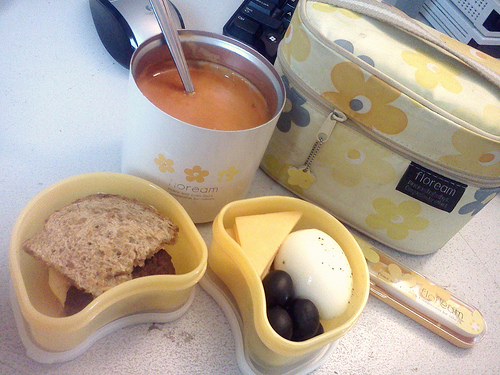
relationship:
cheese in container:
[231, 209, 304, 281] [208, 194, 370, 369]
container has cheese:
[208, 194, 370, 369] [231, 209, 304, 281]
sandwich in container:
[23, 192, 180, 315] [7, 170, 209, 353]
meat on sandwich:
[62, 248, 175, 315] [23, 192, 180, 315]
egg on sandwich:
[47, 269, 70, 307] [23, 192, 180, 315]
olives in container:
[265, 270, 324, 340] [208, 194, 370, 369]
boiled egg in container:
[273, 229, 352, 319] [208, 194, 370, 369]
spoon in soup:
[149, 0, 194, 94] [139, 55, 270, 130]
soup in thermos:
[139, 55, 270, 130] [125, 28, 287, 225]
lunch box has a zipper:
[260, 1, 499, 258] [271, 45, 498, 192]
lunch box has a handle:
[260, 1, 499, 258] [320, 0, 499, 87]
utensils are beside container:
[349, 229, 483, 350] [208, 194, 370, 369]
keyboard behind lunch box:
[224, 1, 300, 65] [260, 1, 499, 258]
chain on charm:
[304, 136, 324, 175] [286, 166, 316, 195]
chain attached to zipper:
[304, 136, 324, 175] [271, 45, 498, 192]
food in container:
[233, 210, 354, 342] [208, 194, 370, 369]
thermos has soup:
[125, 28, 287, 225] [139, 55, 270, 130]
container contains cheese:
[208, 194, 370, 369] [231, 209, 304, 281]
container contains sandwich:
[7, 170, 209, 353] [23, 192, 180, 315]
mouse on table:
[89, 0, 185, 70] [0, 2, 498, 374]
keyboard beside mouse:
[224, 1, 300, 65] [89, 0, 185, 70]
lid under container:
[199, 267, 339, 372] [208, 194, 370, 369]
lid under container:
[8, 279, 198, 366] [7, 170, 209, 353]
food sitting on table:
[24, 193, 356, 339] [0, 2, 498, 374]